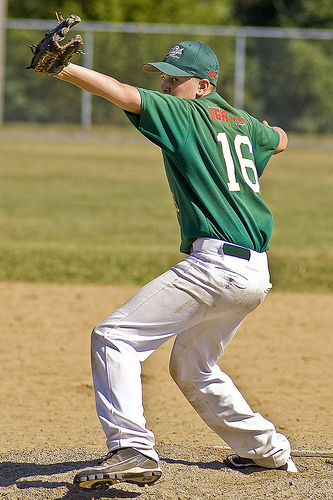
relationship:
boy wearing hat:
[27, 10, 296, 492] [142, 40, 219, 89]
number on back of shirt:
[213, 130, 260, 194] [126, 86, 281, 254]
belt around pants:
[220, 243, 253, 261] [88, 237, 291, 471]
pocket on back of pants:
[209, 266, 246, 308] [88, 237, 291, 471]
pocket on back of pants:
[255, 282, 271, 307] [88, 237, 291, 471]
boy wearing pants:
[27, 10, 296, 492] [88, 237, 291, 471]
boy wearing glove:
[27, 10, 296, 492] [27, 10, 86, 79]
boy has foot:
[27, 10, 296, 492] [223, 452, 299, 474]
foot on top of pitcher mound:
[223, 452, 299, 474] [1, 445, 331, 500]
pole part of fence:
[233, 32, 246, 126] [2, 17, 332, 152]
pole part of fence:
[79, 28, 94, 138] [2, 17, 332, 152]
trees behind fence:
[7, 1, 332, 134] [2, 17, 332, 152]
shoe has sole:
[71, 446, 162, 492] [76, 469, 161, 491]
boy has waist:
[27, 10, 296, 492] [181, 218, 272, 264]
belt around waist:
[220, 243, 253, 261] [181, 218, 272, 264]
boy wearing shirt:
[27, 10, 296, 492] [126, 86, 281, 254]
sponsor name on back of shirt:
[209, 105, 247, 129] [126, 86, 281, 254]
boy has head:
[27, 10, 296, 492] [159, 41, 219, 105]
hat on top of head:
[142, 40, 219, 89] [159, 41, 219, 105]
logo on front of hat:
[163, 42, 185, 63] [142, 40, 219, 89]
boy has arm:
[27, 10, 296, 492] [54, 63, 142, 114]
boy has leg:
[27, 10, 296, 492] [85, 264, 215, 444]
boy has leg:
[27, 10, 296, 492] [167, 312, 274, 454]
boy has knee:
[27, 10, 296, 492] [90, 319, 106, 348]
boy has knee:
[27, 10, 296, 492] [166, 351, 184, 385]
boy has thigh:
[27, 10, 296, 492] [111, 278, 172, 322]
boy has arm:
[27, 10, 296, 492] [251, 119, 289, 156]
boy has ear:
[27, 10, 296, 492] [194, 77, 211, 97]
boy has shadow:
[27, 10, 296, 492] [1, 456, 227, 500]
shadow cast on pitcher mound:
[1, 456, 227, 500] [1, 445, 331, 500]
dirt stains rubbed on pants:
[88, 282, 260, 417] [88, 237, 291, 471]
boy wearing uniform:
[27, 10, 296, 492] [89, 86, 291, 468]